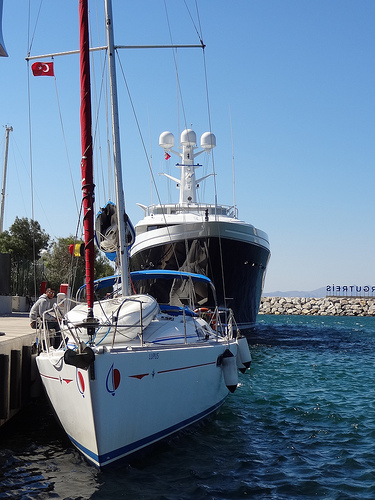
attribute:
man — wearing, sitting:
[12, 282, 67, 332]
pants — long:
[41, 330, 69, 355]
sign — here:
[314, 265, 371, 308]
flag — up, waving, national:
[21, 42, 75, 97]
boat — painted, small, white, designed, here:
[77, 339, 225, 477]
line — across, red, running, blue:
[110, 53, 194, 198]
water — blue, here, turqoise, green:
[214, 387, 373, 475]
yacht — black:
[166, 212, 373, 361]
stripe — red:
[133, 361, 208, 386]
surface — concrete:
[6, 305, 35, 345]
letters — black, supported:
[8, 351, 51, 419]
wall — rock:
[268, 294, 344, 324]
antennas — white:
[148, 102, 229, 171]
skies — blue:
[209, 17, 282, 90]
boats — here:
[48, 118, 299, 415]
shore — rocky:
[260, 287, 300, 313]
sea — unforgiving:
[256, 318, 371, 397]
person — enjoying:
[35, 267, 65, 321]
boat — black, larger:
[141, 231, 221, 279]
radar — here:
[141, 130, 227, 152]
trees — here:
[7, 210, 77, 264]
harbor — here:
[59, 75, 359, 440]